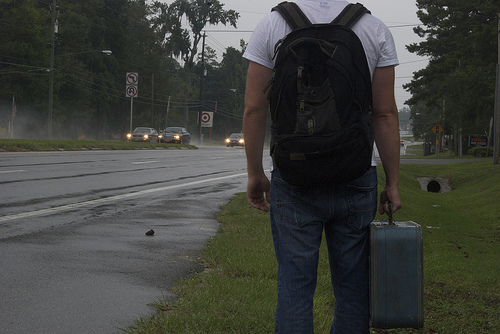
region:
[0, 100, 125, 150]
steam coming of the road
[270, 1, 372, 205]
a black backpack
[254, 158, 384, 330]
a pair of blue jeans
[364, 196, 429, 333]
a grey suitcase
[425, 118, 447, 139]
yellow traffic light sign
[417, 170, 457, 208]
cement sewer drain in a ditch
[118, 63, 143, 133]
white no turn street sign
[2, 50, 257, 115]
row of three electrical lines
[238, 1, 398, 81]
back of a white tee shirt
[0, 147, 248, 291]
a wet road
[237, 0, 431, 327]
a man with a suitcase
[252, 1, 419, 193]
a man with a backpack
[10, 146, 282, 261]
a wet road from rain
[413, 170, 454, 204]
a water drainage pipe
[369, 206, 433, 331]
an older blue suitcase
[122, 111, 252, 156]
three cars with there headlights on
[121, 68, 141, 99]
two signs saying things to not do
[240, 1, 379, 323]
a man wearing jeans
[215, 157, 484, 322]
green grass growing next to the road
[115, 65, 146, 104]
Two traffic signs posted together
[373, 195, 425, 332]
A blue luggage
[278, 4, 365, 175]
A black backpack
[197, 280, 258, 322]
A grassy lawn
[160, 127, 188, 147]
A car with headlights on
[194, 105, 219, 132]
A Target traffic sign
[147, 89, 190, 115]
A series of power lines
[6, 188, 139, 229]
Muddy road with water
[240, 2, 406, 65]
A white t-shirt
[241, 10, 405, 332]
A man walking on the lawn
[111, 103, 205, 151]
Cars driving on the road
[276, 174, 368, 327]
Dark blue denim jeans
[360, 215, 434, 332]
Blue suitcase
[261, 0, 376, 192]
Black and khaki backpack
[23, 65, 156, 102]
No U turn signs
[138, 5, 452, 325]
Guy walking with suitcase and backpack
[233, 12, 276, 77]
White t-shirt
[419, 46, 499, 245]
Green trees and grass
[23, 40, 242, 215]
Cars driving in the rain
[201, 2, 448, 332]
Man leaving with luggage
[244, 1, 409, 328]
this is a man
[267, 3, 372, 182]
he has a bag on his back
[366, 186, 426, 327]
the right hand is carrying a suitcase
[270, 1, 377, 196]
the bag is black in color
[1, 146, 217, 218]
a white line is drawn in middle of the road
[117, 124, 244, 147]
these are cars moving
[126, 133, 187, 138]
the front lights are on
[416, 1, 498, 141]
the trees are beside the road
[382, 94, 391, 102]
the man is light skin in color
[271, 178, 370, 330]
he has worn blue jeabd